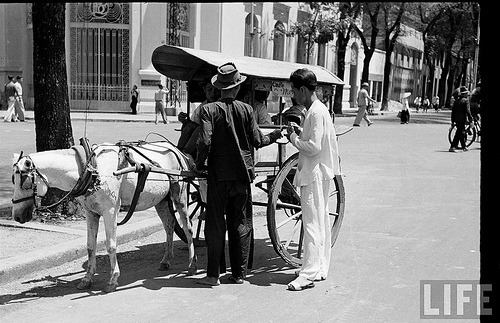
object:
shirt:
[183, 97, 269, 186]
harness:
[13, 138, 200, 222]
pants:
[205, 172, 252, 286]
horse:
[12, 139, 209, 292]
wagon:
[142, 31, 352, 278]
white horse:
[9, 138, 200, 291]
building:
[1, 0, 478, 110]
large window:
[67, 0, 132, 112]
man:
[280, 69, 340, 293]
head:
[10, 151, 45, 225]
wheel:
[266, 151, 342, 269]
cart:
[147, 42, 345, 271]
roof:
[151, 42, 344, 87]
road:
[351, 154, 454, 287]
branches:
[353, 7, 378, 52]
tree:
[323, 0, 352, 109]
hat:
[211, 61, 248, 89]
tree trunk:
[20, 4, 82, 209]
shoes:
[286, 276, 315, 290]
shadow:
[86, 216, 305, 289]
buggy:
[150, 42, 345, 270]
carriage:
[146, 42, 351, 274]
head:
[208, 62, 246, 97]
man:
[197, 61, 266, 283]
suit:
[191, 102, 263, 275]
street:
[1, 108, 481, 321]